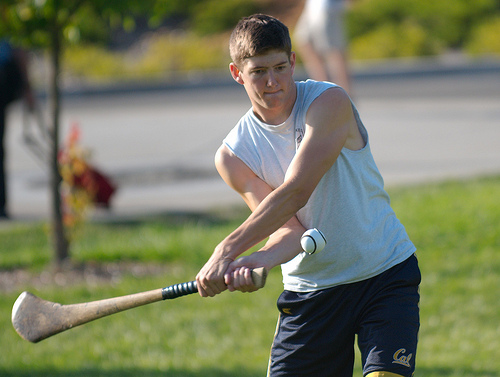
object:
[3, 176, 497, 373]
field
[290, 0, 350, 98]
person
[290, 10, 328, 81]
leg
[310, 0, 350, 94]
leg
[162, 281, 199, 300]
grip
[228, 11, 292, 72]
hair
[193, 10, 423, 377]
boy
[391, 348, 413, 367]
cal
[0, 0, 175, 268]
tree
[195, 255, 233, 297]
hand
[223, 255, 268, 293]
hand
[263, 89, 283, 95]
mouth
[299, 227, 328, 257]
black stripes ball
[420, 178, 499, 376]
green grass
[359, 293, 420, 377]
person's legs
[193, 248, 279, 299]
boy holding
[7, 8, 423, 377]
man is playing ball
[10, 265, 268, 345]
bat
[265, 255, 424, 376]
blue shorts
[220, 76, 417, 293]
boy's shirt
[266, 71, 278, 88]
nose of a man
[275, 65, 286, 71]
eye of a man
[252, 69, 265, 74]
eye of a man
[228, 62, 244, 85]
ear of a man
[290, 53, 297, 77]
ear of a man